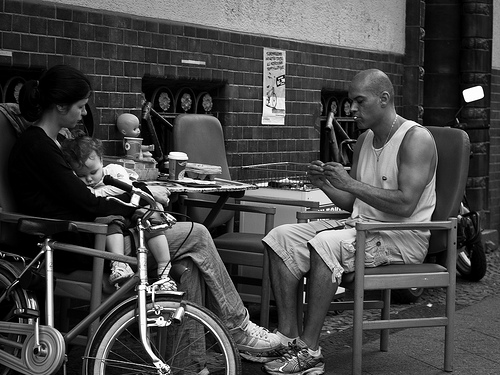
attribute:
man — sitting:
[262, 66, 441, 367]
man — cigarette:
[253, 62, 460, 372]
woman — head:
[10, 51, 95, 131]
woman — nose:
[74, 104, 92, 117]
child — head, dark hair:
[79, 136, 187, 315]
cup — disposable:
[166, 145, 190, 175]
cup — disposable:
[158, 140, 190, 180]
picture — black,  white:
[252, 52, 302, 122]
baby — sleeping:
[76, 138, 188, 310]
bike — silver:
[9, 162, 246, 372]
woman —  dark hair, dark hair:
[12, 62, 298, 367]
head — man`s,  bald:
[344, 68, 401, 135]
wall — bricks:
[80, 24, 277, 116]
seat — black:
[4, 182, 77, 266]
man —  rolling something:
[306, 130, 345, 199]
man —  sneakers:
[258, 329, 332, 372]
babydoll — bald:
[103, 110, 162, 188]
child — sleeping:
[75, 129, 180, 303]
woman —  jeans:
[104, 218, 262, 373]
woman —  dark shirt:
[1, 116, 139, 249]